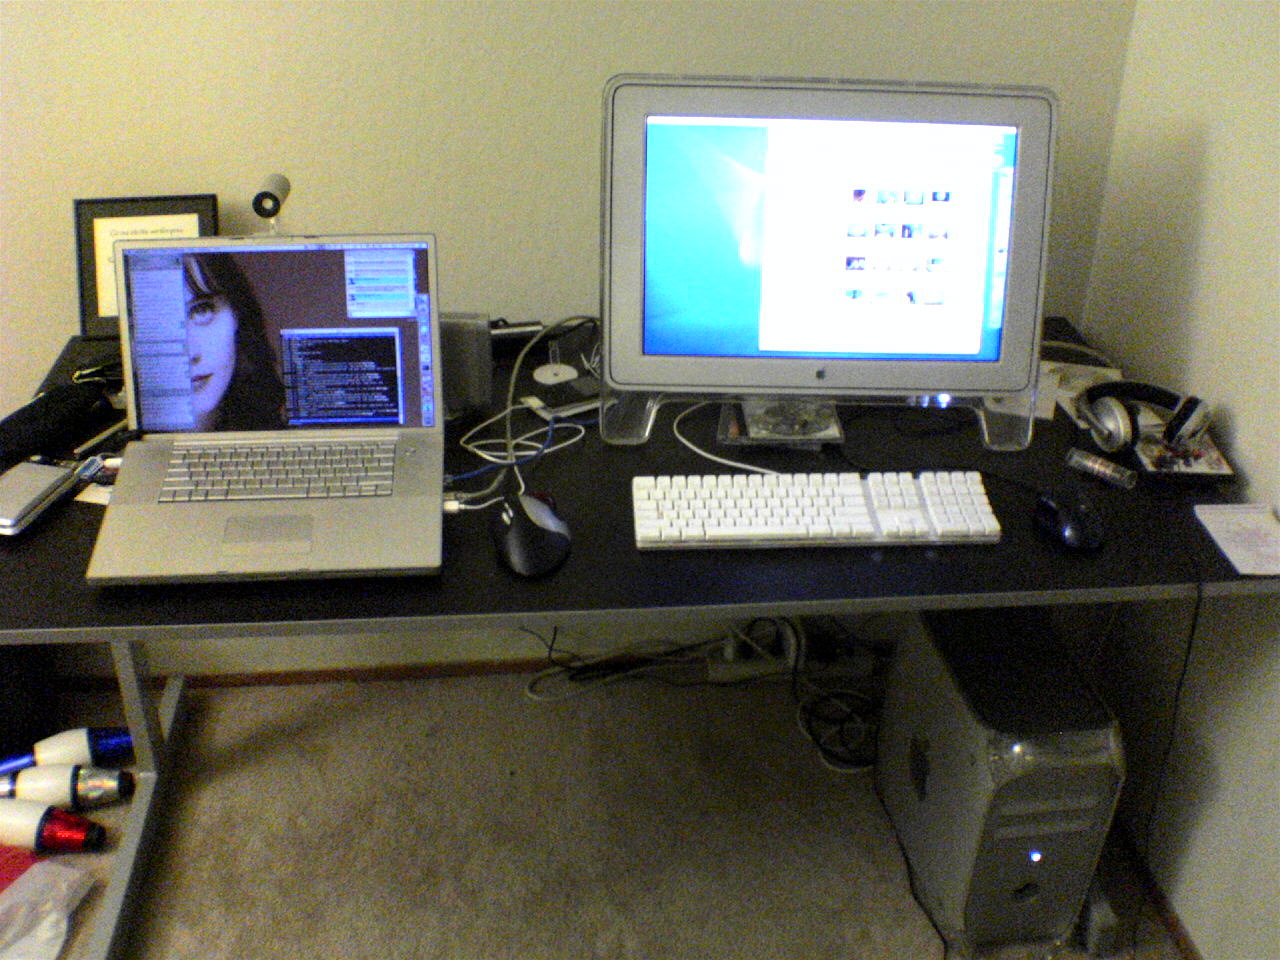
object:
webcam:
[250, 174, 289, 236]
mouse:
[502, 487, 573, 576]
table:
[0, 300, 1280, 646]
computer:
[85, 230, 445, 590]